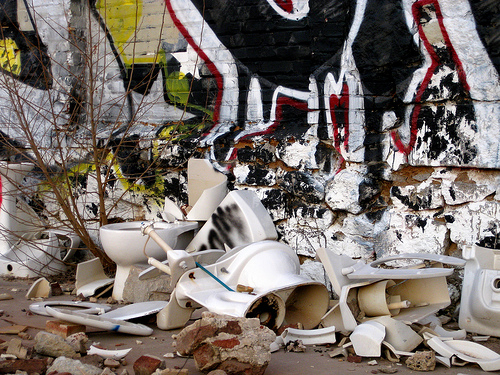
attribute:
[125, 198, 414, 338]
toilet — broken, white, lid , blue paint,  seat, upside down, tank, spray paint, spray , tipped  , bottom   , seat    ,   seat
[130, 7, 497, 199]
wall — brick, painted, white , old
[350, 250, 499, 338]
sink — broken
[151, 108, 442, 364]
toilets — broken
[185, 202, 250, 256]
mom — spray painted, black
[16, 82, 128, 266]
tree — small dead , leafless, no leaves, growing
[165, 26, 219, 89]
star — white , trimmed in yellow 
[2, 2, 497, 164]
painting — some , white paint,  black paint,   red paint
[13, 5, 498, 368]
scene — daytime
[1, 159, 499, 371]
seat lids — broken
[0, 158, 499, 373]
fixtures — broken, bathroom fixtures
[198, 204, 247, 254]
mom — spray painted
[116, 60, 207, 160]
star — spray painted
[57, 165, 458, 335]
toilets — broken  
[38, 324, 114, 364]
rock — big   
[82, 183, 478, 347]
graffiti — black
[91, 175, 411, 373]
seat — toilet 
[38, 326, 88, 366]
rock — small 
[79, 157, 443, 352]
paint — spray 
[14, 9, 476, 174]
painting — some